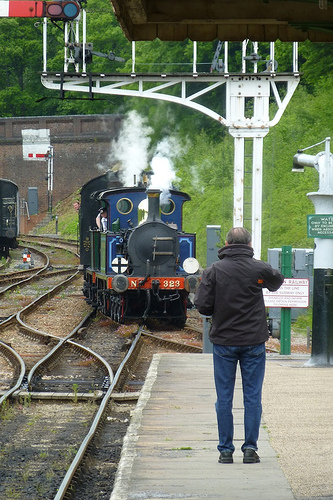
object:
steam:
[93, 105, 156, 189]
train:
[78, 171, 197, 335]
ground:
[0, 234, 333, 499]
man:
[194, 228, 286, 465]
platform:
[108, 351, 332, 498]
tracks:
[142, 323, 204, 356]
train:
[0, 178, 21, 263]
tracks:
[0, 254, 11, 271]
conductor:
[98, 206, 109, 230]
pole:
[279, 247, 291, 357]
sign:
[260, 278, 309, 308]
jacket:
[192, 244, 286, 349]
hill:
[29, 45, 333, 330]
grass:
[171, 73, 333, 272]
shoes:
[217, 448, 235, 464]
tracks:
[0, 313, 115, 499]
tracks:
[1, 239, 84, 332]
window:
[115, 197, 132, 215]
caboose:
[77, 174, 128, 267]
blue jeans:
[212, 342, 266, 452]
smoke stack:
[143, 189, 161, 220]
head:
[99, 208, 111, 218]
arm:
[259, 260, 286, 293]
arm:
[195, 265, 215, 317]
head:
[223, 228, 252, 246]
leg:
[242, 343, 266, 452]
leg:
[214, 343, 238, 450]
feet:
[243, 447, 261, 463]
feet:
[218, 446, 234, 464]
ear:
[224, 238, 229, 246]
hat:
[98, 205, 107, 214]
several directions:
[0, 232, 204, 498]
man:
[72, 200, 81, 214]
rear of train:
[80, 169, 128, 268]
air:
[282, 380, 332, 472]